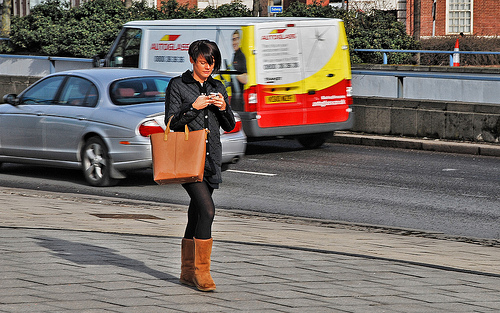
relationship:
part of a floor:
[258, 250, 281, 285] [256, 243, 273, 257]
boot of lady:
[194, 237, 214, 290] [150, 40, 235, 293]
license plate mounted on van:
[260, 82, 298, 104] [94, 10, 361, 145]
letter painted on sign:
[271, 6, 273, 11] [268, 3, 283, 13]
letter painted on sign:
[274, 7, 277, 8] [268, 3, 283, 13]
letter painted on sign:
[275, 8, 276, 9] [268, 3, 283, 13]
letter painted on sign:
[277, 7, 278, 10] [268, 3, 283, 13]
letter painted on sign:
[279, 7, 280, 9] [268, 3, 283, 13]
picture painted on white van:
[215, 29, 252, 111] [120, 18, 353, 134]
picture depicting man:
[215, 29, 252, 111] [222, 30, 246, 110]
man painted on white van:
[222, 30, 246, 110] [120, 18, 353, 134]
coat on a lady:
[171, 78, 193, 105] [135, 26, 264, 311]